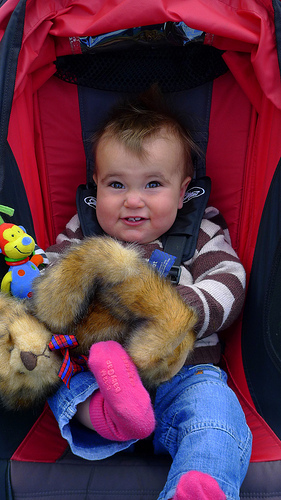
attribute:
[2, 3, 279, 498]
stroller — red, plastic, black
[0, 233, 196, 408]
bear — brown, stuffed, toy, colorful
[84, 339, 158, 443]
sock — pink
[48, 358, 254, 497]
jeans — blue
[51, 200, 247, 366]
shirt — red, striped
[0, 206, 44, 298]
bug — yellow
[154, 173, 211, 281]
strap — black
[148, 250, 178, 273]
tag — blue